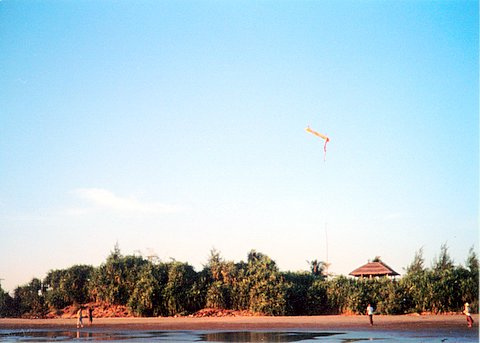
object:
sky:
[0, 1, 479, 274]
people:
[75, 302, 474, 327]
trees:
[0, 242, 480, 313]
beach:
[2, 315, 479, 329]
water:
[2, 324, 477, 342]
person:
[362, 301, 377, 324]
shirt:
[366, 306, 373, 315]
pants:
[366, 313, 376, 323]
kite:
[304, 125, 331, 162]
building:
[347, 256, 402, 280]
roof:
[350, 256, 398, 275]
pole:
[363, 273, 375, 280]